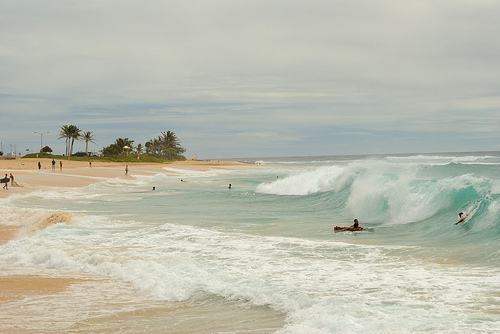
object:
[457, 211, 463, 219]
person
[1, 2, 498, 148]
clouds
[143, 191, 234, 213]
water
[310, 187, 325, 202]
ground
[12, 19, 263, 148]
sky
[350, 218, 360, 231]
someone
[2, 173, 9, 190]
person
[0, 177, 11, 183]
surfboard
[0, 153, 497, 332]
beach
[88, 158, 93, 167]
person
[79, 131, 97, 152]
palmtrees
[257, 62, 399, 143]
sky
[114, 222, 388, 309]
tide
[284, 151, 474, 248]
water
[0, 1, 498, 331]
tropical region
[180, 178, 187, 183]
people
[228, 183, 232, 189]
people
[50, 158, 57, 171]
people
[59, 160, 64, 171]
person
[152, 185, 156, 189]
people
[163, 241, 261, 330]
water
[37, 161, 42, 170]
people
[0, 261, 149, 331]
water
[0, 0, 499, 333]
scene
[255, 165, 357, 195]
surf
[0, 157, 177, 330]
sand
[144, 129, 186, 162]
vegetation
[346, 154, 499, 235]
wave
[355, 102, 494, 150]
sky